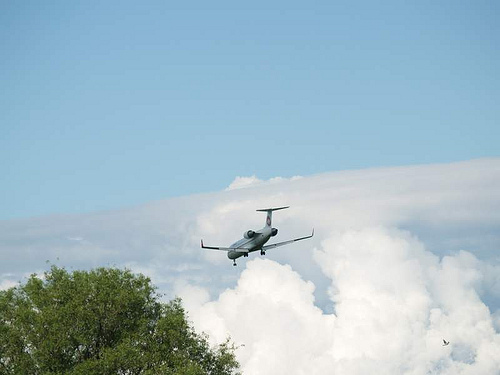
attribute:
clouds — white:
[4, 155, 496, 373]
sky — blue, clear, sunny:
[1, 1, 497, 367]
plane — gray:
[194, 190, 350, 280]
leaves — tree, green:
[112, 298, 156, 335]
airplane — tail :
[192, 200, 319, 269]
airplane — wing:
[174, 197, 315, 257]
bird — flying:
[413, 325, 477, 353]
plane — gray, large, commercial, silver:
[199, 202, 318, 270]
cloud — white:
[185, 256, 339, 370]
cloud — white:
[308, 218, 442, 372]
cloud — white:
[427, 248, 498, 372]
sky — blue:
[2, 3, 496, 227]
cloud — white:
[170, 258, 329, 373]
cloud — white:
[310, 221, 440, 357]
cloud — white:
[428, 250, 498, 352]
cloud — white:
[314, 226, 452, 359]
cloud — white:
[211, 254, 340, 371]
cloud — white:
[432, 256, 492, 344]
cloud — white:
[192, 173, 322, 262]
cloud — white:
[432, 242, 498, 354]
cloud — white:
[173, 253, 338, 371]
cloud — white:
[472, 330, 498, 372]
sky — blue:
[1, 2, 499, 322]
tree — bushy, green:
[1, 260, 244, 373]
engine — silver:
[242, 230, 259, 240]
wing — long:
[194, 240, 230, 255]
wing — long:
[264, 225, 315, 249]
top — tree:
[6, 262, 239, 367]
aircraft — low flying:
[190, 201, 327, 263]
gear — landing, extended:
[232, 256, 239, 272]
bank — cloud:
[14, 167, 483, 300]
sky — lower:
[5, 8, 484, 273]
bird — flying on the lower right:
[434, 333, 456, 349]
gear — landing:
[228, 256, 238, 266]